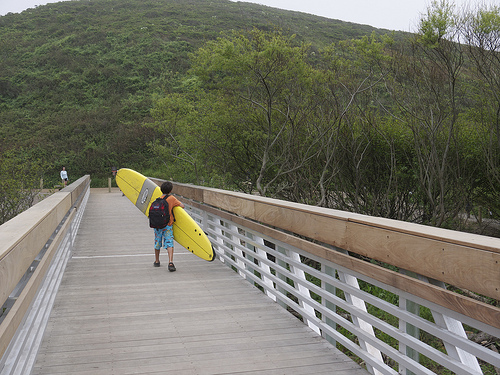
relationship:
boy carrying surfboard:
[108, 161, 214, 286] [108, 162, 218, 264]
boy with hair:
[135, 168, 193, 287] [155, 174, 175, 198]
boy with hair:
[108, 161, 214, 286] [158, 177, 176, 199]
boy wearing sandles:
[108, 161, 214, 286] [137, 244, 185, 273]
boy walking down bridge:
[108, 161, 214, 286] [0, 174, 498, 371]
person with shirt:
[75, 183, 242, 300] [56, 167, 71, 177]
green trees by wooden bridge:
[1, 7, 495, 224] [2, 166, 497, 370]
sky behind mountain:
[2, 1, 499, 49] [0, 4, 498, 176]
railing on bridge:
[149, 170, 495, 374] [15, 115, 498, 347]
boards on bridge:
[106, 163, 216, 274] [0, 174, 498, 371]